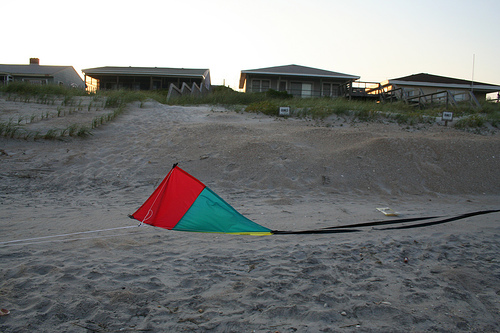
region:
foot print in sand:
[67, 303, 97, 321]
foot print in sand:
[123, 301, 160, 323]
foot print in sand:
[14, 298, 55, 318]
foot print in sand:
[27, 261, 54, 281]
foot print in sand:
[358, 303, 400, 323]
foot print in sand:
[314, 275, 337, 287]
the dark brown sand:
[119, 285, 156, 303]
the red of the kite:
[149, 190, 173, 209]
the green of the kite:
[196, 207, 224, 223]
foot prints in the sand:
[291, 250, 331, 281]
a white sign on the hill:
[274, 102, 303, 126]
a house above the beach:
[241, 71, 336, 99]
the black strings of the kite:
[319, 218, 334, 232]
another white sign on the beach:
[438, 110, 458, 131]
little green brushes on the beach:
[57, 104, 81, 121]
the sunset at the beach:
[81, 75, 96, 87]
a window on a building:
[122, 80, 136, 94]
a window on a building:
[248, 75, 265, 93]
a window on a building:
[258, 79, 268, 91]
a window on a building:
[302, 83, 309, 92]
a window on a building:
[322, 86, 334, 97]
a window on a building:
[331, 83, 336, 95]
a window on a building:
[406, 90, 423, 107]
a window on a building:
[101, 80, 114, 88]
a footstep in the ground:
[141, 282, 162, 294]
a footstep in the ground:
[175, 275, 207, 290]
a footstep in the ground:
[306, 277, 332, 305]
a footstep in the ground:
[403, 286, 430, 312]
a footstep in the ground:
[339, 300, 383, 322]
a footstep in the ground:
[421, 312, 454, 325]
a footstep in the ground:
[268, 304, 303, 317]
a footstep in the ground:
[60, 277, 82, 289]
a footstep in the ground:
[25, 266, 62, 279]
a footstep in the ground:
[36, 299, 58, 311]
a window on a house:
[248, 78, 264, 98]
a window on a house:
[278, 79, 290, 91]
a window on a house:
[306, 83, 318, 105]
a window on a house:
[323, 82, 331, 99]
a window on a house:
[332, 82, 344, 96]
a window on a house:
[408, 91, 424, 103]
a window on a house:
[436, 93, 455, 105]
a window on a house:
[153, 76, 165, 93]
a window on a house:
[112, 78, 130, 88]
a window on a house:
[129, 81, 149, 90]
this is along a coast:
[34, 81, 459, 268]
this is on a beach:
[144, 128, 462, 285]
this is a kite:
[91, 135, 305, 240]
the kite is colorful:
[115, 140, 332, 265]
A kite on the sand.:
[120, 162, 493, 244]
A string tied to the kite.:
[15, 184, 168, 259]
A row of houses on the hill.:
[1, 55, 498, 114]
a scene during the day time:
[1, 3, 498, 328]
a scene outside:
[2, 7, 497, 327]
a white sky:
[5, 0, 495, 81]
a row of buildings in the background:
[5, 46, 496, 136]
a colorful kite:
[0, 155, 495, 291]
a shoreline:
[20, 172, 496, 328]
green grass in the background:
[57, 75, 494, 145]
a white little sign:
[268, 102, 297, 117]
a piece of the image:
[95, 194, 97, 201]